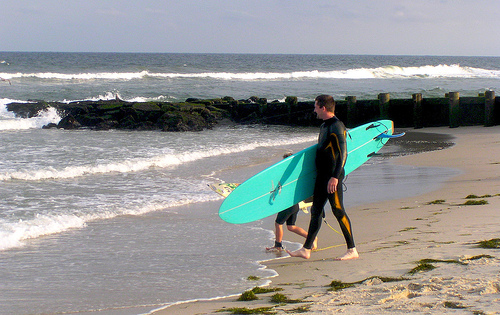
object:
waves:
[1, 66, 498, 258]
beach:
[138, 124, 497, 314]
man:
[287, 94, 360, 262]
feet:
[285, 248, 360, 261]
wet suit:
[303, 117, 356, 251]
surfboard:
[217, 119, 407, 226]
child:
[267, 203, 319, 250]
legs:
[266, 225, 318, 255]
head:
[314, 94, 335, 121]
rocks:
[59, 100, 237, 133]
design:
[325, 132, 354, 238]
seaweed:
[237, 191, 500, 315]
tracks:
[375, 236, 460, 249]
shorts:
[274, 202, 297, 227]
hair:
[314, 95, 337, 113]